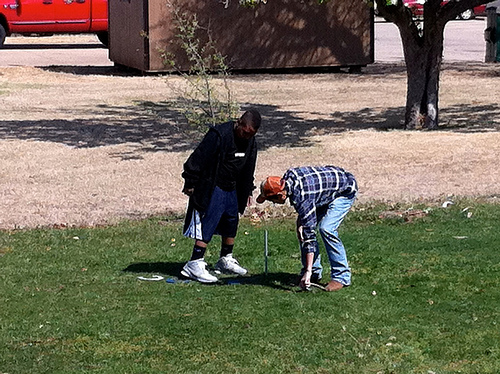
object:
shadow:
[0, 96, 500, 165]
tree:
[363, 0, 500, 139]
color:
[180, 258, 219, 284]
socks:
[191, 241, 235, 260]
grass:
[1, 203, 498, 373]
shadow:
[204, 272, 328, 293]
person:
[256, 166, 358, 293]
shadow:
[123, 261, 197, 280]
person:
[181, 108, 261, 283]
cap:
[256, 176, 285, 204]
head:
[256, 176, 290, 204]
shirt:
[256, 164, 358, 292]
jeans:
[296, 193, 356, 286]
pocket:
[188, 178, 215, 214]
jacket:
[181, 120, 257, 214]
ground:
[299, 270, 312, 289]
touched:
[301, 282, 325, 292]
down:
[266, 192, 287, 204]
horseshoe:
[137, 275, 165, 281]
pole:
[264, 228, 268, 278]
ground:
[245, 269, 287, 286]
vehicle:
[0, 0, 113, 50]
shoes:
[180, 253, 248, 283]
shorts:
[183, 181, 240, 241]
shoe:
[323, 276, 345, 291]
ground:
[124, 264, 180, 294]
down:
[235, 121, 257, 141]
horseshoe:
[300, 282, 330, 292]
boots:
[301, 268, 345, 292]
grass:
[0, 68, 500, 230]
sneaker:
[180, 257, 219, 283]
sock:
[190, 244, 207, 261]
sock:
[220, 244, 234, 259]